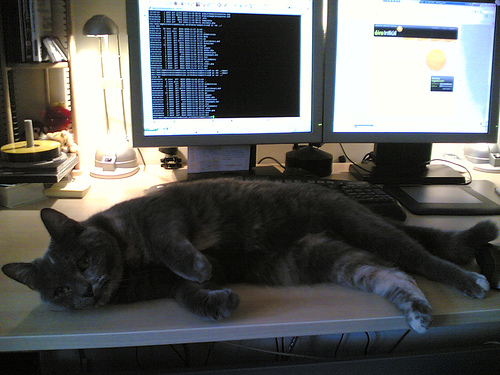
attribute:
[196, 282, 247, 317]
paws — cat's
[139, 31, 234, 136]
letters — blue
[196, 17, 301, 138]
background — black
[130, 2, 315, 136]
screen — computer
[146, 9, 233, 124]
lettering — white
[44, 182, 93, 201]
paper — pad, small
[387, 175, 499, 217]
mouse pad — grey, black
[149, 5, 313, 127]
monitor — computer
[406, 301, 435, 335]
foot — cat's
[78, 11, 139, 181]
desk lamp — on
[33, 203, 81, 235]
ear — black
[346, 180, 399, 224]
keyboard — black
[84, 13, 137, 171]
lamp — lit, desk top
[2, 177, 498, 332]
cat — sideways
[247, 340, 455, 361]
cords — electrical